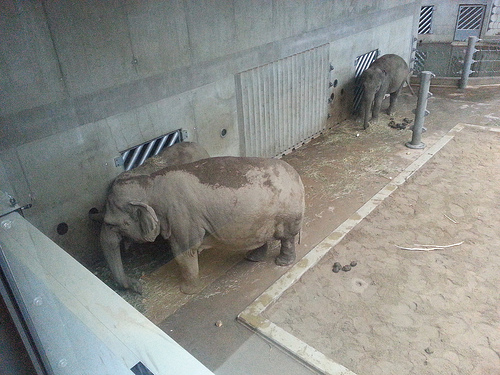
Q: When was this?
A: Daytime.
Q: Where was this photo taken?
A: In an elephant enclosure.